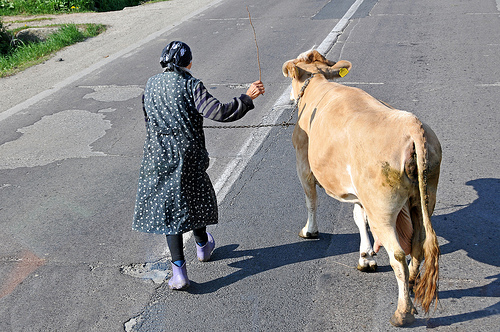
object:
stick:
[245, 5, 263, 83]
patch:
[0, 18, 49, 60]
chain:
[201, 74, 315, 129]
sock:
[174, 261, 182, 267]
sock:
[197, 242, 203, 246]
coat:
[132, 66, 256, 235]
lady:
[131, 40, 266, 291]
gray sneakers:
[167, 259, 191, 290]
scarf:
[159, 41, 192, 79]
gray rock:
[15, 27, 60, 41]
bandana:
[159, 40, 196, 80]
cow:
[282, 49, 444, 327]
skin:
[319, 105, 351, 135]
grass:
[0, 1, 157, 79]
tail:
[410, 131, 444, 327]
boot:
[168, 259, 190, 290]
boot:
[194, 232, 215, 261]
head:
[159, 40, 193, 71]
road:
[6, 0, 500, 332]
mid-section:
[153, 125, 171, 135]